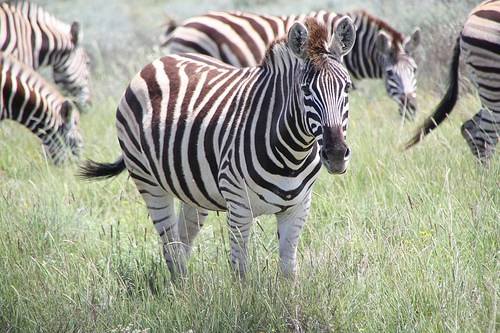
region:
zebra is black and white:
[106, 50, 471, 285]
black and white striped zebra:
[123, 17, 350, 274]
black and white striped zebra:
[422, 2, 499, 139]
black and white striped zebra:
[158, 4, 428, 119]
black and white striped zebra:
[13, 62, 88, 189]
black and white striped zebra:
[7, 6, 107, 113]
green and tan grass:
[13, 178, 140, 322]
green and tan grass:
[338, 207, 477, 317]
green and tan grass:
[363, 121, 398, 316]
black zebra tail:
[81, 148, 125, 191]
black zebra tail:
[419, 20, 461, 175]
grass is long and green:
[41, 213, 498, 303]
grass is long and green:
[68, 183, 358, 288]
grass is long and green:
[134, 235, 348, 323]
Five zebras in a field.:
[0, 5, 493, 302]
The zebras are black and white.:
[0, 1, 485, 289]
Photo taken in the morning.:
[7, 2, 490, 324]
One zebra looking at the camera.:
[110, 22, 394, 299]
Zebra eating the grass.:
[7, 77, 102, 202]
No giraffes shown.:
[0, 15, 492, 326]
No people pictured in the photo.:
[7, 6, 490, 324]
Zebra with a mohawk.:
[251, 33, 345, 85]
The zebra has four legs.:
[96, 159, 340, 312]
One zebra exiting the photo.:
[422, 2, 499, 181]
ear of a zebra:
[281, 18, 313, 58]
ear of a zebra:
[330, 16, 368, 53]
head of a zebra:
[282, 10, 382, 179]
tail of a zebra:
[400, 37, 470, 148]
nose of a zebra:
[318, 127, 350, 174]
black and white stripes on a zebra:
[167, 62, 235, 106]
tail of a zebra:
[76, 138, 127, 189]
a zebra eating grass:
[36, 109, 88, 196]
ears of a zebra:
[373, 22, 430, 57]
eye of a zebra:
[296, 81, 314, 100]